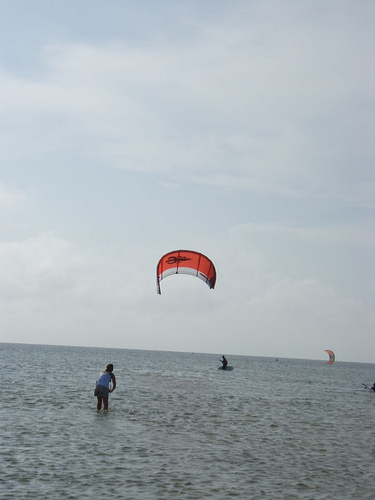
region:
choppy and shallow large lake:
[2, 342, 374, 497]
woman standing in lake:
[92, 361, 116, 414]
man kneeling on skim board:
[217, 353, 235, 372]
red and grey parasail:
[156, 247, 216, 298]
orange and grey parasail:
[323, 346, 337, 365]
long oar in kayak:
[361, 379, 373, 395]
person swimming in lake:
[275, 357, 279, 363]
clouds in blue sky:
[2, 5, 373, 366]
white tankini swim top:
[96, 369, 113, 390]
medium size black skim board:
[219, 365, 233, 372]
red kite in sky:
[152, 247, 217, 297]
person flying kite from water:
[92, 247, 216, 412]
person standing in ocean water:
[90, 360, 115, 409]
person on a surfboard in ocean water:
[214, 352, 235, 373]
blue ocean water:
[194, 417, 279, 475]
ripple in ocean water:
[177, 407, 202, 419]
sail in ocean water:
[319, 346, 338, 366]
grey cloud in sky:
[20, 231, 79, 265]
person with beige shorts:
[92, 383, 110, 399]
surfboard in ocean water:
[216, 364, 234, 372]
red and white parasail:
[102, 221, 250, 336]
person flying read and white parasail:
[29, 246, 223, 426]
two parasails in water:
[140, 227, 345, 379]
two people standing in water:
[73, 337, 276, 424]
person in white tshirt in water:
[92, 349, 141, 430]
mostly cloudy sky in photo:
[5, 107, 331, 340]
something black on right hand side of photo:
[350, 342, 374, 395]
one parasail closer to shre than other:
[122, 238, 347, 381]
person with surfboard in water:
[201, 339, 242, 383]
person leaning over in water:
[57, 344, 158, 439]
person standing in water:
[83, 356, 140, 417]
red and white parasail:
[143, 242, 232, 301]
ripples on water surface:
[173, 402, 269, 454]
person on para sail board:
[213, 348, 242, 375]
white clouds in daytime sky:
[253, 223, 339, 311]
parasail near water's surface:
[318, 344, 339, 372]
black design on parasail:
[162, 250, 195, 268]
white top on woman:
[88, 368, 115, 391]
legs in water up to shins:
[92, 393, 114, 415]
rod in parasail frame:
[190, 250, 207, 282]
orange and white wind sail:
[149, 245, 228, 301]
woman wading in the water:
[89, 363, 125, 412]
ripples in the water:
[140, 408, 219, 468]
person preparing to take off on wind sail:
[212, 354, 240, 378]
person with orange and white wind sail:
[215, 341, 354, 389]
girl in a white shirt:
[84, 358, 129, 426]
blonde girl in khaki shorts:
[87, 357, 129, 417]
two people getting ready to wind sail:
[67, 332, 277, 447]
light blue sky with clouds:
[46, 155, 134, 271]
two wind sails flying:
[146, 242, 346, 365]